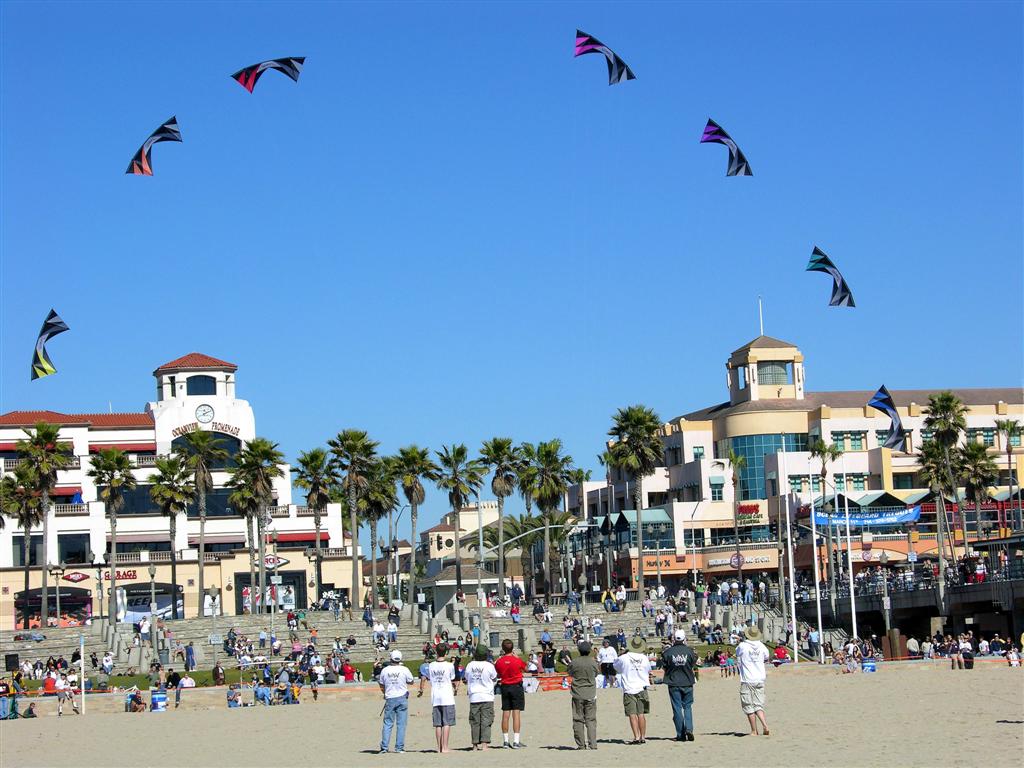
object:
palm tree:
[148, 431, 339, 641]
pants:
[584, 619, 604, 628]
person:
[729, 624, 775, 737]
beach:
[0, 668, 1019, 768]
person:
[375, 647, 411, 753]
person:
[599, 633, 618, 689]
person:
[654, 629, 706, 741]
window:
[147, 542, 179, 577]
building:
[0, 351, 365, 632]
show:
[16, 20, 920, 486]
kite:
[300, 176, 360, 237]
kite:
[225, 56, 308, 104]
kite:
[569, 24, 641, 94]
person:
[425, 643, 458, 746]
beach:
[9, 662, 990, 764]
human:
[614, 636, 653, 744]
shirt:
[495, 653, 522, 688]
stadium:
[0, 300, 1024, 632]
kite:
[693, 113, 754, 177]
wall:
[170, 505, 187, 549]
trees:
[0, 404, 668, 628]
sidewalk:
[0, 604, 829, 673]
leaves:
[367, 481, 399, 518]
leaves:
[0, 419, 143, 524]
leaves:
[381, 444, 442, 505]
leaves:
[291, 445, 332, 489]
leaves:
[603, 405, 668, 478]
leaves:
[433, 445, 488, 509]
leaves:
[227, 487, 263, 514]